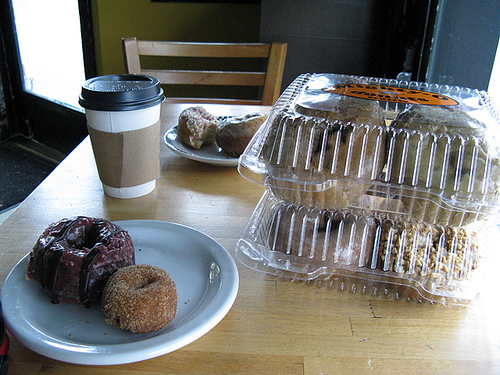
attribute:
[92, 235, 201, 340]
donut — brown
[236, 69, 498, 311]
boxes — plastic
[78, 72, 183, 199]
cup — brown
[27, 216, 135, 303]
doughnut — chocolate covered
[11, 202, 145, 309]
donut — brown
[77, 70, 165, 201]
cup — travel coffee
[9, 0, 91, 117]
window — brown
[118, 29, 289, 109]
chair — wooden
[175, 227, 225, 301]
plate — white 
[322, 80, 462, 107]
sticker — orange 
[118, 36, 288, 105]
chair — wooden 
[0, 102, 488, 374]
table top — tan, wooden 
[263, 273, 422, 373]
table — light brown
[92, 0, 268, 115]
paint — yellow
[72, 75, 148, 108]
lid — black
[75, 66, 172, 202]
cup — white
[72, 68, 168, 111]
top — black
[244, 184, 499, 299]
container — plastic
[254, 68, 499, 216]
container — plastic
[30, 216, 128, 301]
frosting — chocolate 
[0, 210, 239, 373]
plate — blue , white, round